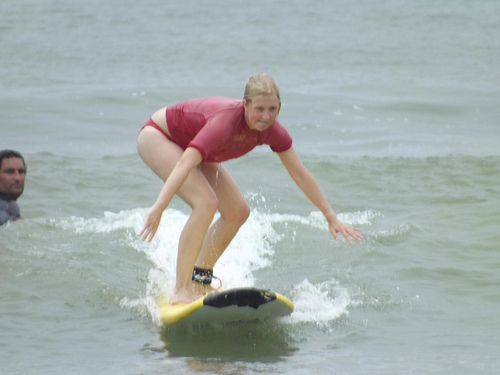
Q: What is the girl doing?
A: Surfing.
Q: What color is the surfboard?
A: Yellow and black.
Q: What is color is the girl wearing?
A: Red.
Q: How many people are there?
A: Two.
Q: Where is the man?
A: In the water.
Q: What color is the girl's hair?
A: Blonde.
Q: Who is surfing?
A: Girl.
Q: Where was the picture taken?
A: Ocean.